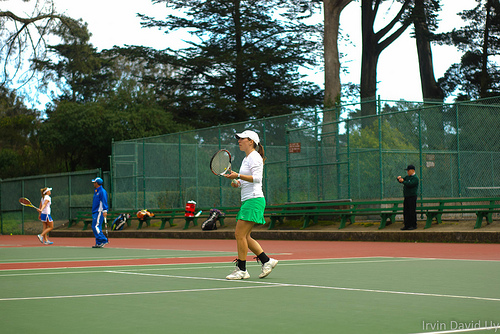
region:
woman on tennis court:
[226, 130, 276, 280]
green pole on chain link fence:
[366, 99, 388, 201]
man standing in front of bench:
[393, 164, 422, 229]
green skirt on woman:
[236, 196, 267, 228]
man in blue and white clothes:
[90, 177, 112, 247]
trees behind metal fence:
[146, 39, 290, 125]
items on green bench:
[110, 198, 227, 235]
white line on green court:
[321, 282, 493, 302]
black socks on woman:
[236, 252, 271, 273]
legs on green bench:
[421, 209, 493, 226]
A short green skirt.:
[234, 199, 272, 223]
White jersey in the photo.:
[237, 155, 266, 201]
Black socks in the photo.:
[256, 251, 268, 265]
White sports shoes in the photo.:
[224, 258, 286, 279]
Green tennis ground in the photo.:
[312, 249, 434, 325]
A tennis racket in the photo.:
[207, 145, 237, 175]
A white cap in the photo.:
[234, 129, 266, 143]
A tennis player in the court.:
[207, 127, 277, 281]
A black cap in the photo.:
[402, 160, 416, 170]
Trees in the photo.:
[325, 0, 446, 100]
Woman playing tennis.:
[208, 118, 279, 283]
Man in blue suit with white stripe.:
[87, 170, 111, 259]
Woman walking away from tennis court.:
[18, 180, 58, 248]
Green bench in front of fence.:
[261, 196, 355, 230]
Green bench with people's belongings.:
[61, 197, 228, 228]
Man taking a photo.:
[392, 160, 425, 234]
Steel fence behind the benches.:
[107, 96, 498, 226]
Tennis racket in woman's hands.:
[207, 147, 245, 191]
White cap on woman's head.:
[235, 125, 263, 155]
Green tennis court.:
[1, 240, 499, 331]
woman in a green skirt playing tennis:
[212, 129, 280, 281]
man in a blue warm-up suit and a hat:
[89, 176, 106, 249]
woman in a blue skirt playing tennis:
[18, 187, 49, 244]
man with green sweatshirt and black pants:
[397, 164, 417, 228]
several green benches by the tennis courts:
[77, 200, 498, 225]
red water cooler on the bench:
[183, 197, 195, 217]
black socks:
[237, 251, 271, 268]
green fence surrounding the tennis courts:
[1, 99, 498, 219]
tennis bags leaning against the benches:
[112, 209, 221, 229]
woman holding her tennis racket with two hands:
[208, 130, 278, 282]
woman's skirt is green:
[227, 185, 275, 227]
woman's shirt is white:
[230, 140, 272, 199]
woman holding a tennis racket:
[200, 129, 266, 197]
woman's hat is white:
[218, 113, 266, 157]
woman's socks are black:
[210, 212, 285, 279]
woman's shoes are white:
[210, 249, 315, 300]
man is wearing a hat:
[389, 139, 435, 236]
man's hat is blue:
[73, 157, 129, 262]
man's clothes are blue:
[82, 191, 121, 261]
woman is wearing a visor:
[21, 168, 61, 238]